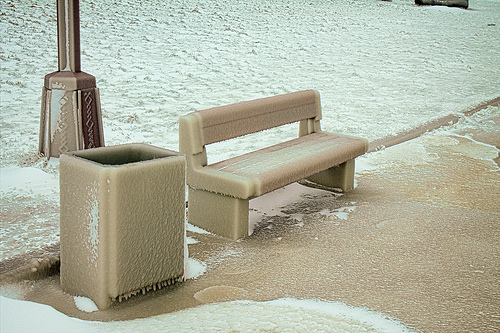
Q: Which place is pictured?
A: It is a sidewalk.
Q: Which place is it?
A: It is a sidewalk.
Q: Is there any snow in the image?
A: Yes, there is snow.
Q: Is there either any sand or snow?
A: Yes, there is snow.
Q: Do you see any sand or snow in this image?
A: Yes, there is snow.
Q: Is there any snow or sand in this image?
A: Yes, there is snow.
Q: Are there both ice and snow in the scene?
A: Yes, there are both snow and ice.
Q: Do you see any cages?
A: No, there are no cages.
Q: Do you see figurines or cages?
A: No, there are no cages or figurines.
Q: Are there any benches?
A: Yes, there is a bench.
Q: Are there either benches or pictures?
A: Yes, there is a bench.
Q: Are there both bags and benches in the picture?
A: No, there is a bench but no bags.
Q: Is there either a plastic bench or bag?
A: Yes, there is a plastic bench.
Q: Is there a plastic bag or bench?
A: Yes, there is a plastic bench.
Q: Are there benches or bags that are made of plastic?
A: Yes, the bench is made of plastic.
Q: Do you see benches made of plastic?
A: Yes, there is a bench that is made of plastic.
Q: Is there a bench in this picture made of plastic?
A: Yes, there is a bench that is made of plastic.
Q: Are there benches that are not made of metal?
A: Yes, there is a bench that is made of plastic.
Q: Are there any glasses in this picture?
A: No, there are no glasses.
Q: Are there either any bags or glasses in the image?
A: No, there are no glasses or bags.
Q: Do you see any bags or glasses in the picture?
A: No, there are no glasses or bags.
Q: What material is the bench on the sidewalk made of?
A: The bench is made of plastic.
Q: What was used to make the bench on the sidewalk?
A: The bench is made of plastic.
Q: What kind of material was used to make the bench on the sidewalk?
A: The bench is made of plastic.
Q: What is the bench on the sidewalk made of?
A: The bench is made of plastic.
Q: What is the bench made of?
A: The bench is made of plastic.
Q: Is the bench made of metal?
A: No, the bench is made of plastic.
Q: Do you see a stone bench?
A: No, there is a bench but it is made of plastic.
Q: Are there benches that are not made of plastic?
A: No, there is a bench but it is made of plastic.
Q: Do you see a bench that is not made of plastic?
A: No, there is a bench but it is made of plastic.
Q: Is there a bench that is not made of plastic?
A: No, there is a bench but it is made of plastic.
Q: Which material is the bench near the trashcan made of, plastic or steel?
A: The bench is made of plastic.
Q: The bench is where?
A: The bench is on the sidewalk.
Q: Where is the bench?
A: The bench is on the sidewalk.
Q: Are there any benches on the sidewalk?
A: Yes, there is a bench on the sidewalk.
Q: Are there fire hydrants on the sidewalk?
A: No, there is a bench on the sidewalk.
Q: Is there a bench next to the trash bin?
A: Yes, there is a bench next to the trash bin.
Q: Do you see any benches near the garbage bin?
A: Yes, there is a bench near the garbage bin.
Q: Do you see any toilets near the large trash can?
A: No, there is a bench near the garbage bin.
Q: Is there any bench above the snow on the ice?
A: Yes, there is a bench above the snow.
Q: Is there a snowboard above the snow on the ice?
A: No, there is a bench above the snow.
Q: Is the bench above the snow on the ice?
A: Yes, the bench is above the snow.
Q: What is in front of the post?
A: The bench is in front of the post.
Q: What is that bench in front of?
A: The bench is in front of the post.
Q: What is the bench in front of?
A: The bench is in front of the post.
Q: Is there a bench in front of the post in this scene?
A: Yes, there is a bench in front of the post.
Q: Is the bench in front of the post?
A: Yes, the bench is in front of the post.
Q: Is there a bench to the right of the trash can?
A: Yes, there is a bench to the right of the trash can.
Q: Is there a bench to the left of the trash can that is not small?
A: No, the bench is to the right of the garbage can.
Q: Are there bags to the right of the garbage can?
A: No, there is a bench to the right of the garbage can.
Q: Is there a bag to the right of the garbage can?
A: No, there is a bench to the right of the garbage can.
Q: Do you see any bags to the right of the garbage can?
A: No, there is a bench to the right of the garbage can.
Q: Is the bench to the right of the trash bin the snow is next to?
A: Yes, the bench is to the right of the garbage bin.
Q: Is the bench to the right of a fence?
A: No, the bench is to the right of the garbage bin.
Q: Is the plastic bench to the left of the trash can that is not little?
A: No, the bench is to the right of the garbage can.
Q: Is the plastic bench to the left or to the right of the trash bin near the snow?
A: The bench is to the right of the trash can.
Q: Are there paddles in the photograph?
A: No, there are no paddles.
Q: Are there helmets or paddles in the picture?
A: No, there are no paddles or helmets.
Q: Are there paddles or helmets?
A: No, there are no paddles or helmets.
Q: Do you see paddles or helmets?
A: No, there are no paddles or helmets.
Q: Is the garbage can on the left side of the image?
A: Yes, the garbage can is on the left of the image.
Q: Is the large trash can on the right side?
A: No, the trashcan is on the left of the image.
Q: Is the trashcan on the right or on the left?
A: The trashcan is on the left of the image.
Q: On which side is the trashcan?
A: The trashcan is on the left of the image.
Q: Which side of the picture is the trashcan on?
A: The trashcan is on the left of the image.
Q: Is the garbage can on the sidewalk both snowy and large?
A: Yes, the trash bin is snowy and large.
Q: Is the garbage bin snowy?
A: Yes, the garbage bin is snowy.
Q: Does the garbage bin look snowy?
A: Yes, the garbage bin is snowy.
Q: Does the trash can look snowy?
A: Yes, the trash can is snowy.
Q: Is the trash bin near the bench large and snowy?
A: Yes, the trash can is large and snowy.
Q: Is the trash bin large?
A: Yes, the trash bin is large.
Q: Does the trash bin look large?
A: Yes, the trash bin is large.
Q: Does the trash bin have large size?
A: Yes, the trash bin is large.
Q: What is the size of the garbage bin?
A: The garbage bin is large.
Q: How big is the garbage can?
A: The garbage can is large.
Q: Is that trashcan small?
A: No, the trashcan is large.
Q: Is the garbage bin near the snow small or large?
A: The garbage can is large.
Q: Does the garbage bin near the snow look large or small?
A: The garbage can is large.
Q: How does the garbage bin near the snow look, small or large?
A: The garbage can is large.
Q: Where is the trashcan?
A: The trashcan is on the sidewalk.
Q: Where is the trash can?
A: The trashcan is on the sidewalk.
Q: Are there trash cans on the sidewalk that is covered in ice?
A: Yes, there is a trash can on the side walk.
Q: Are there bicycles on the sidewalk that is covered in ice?
A: No, there is a trash can on the side walk.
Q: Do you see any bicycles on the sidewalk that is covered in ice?
A: No, there is a trash can on the side walk.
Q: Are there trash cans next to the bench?
A: Yes, there is a trash can next to the bench.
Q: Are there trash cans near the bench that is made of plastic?
A: Yes, there is a trash can near the bench.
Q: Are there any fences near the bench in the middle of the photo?
A: No, there is a trash can near the bench.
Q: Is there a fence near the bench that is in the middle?
A: No, there is a trash can near the bench.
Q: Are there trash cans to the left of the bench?
A: Yes, there is a trash can to the left of the bench.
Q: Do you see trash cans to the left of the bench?
A: Yes, there is a trash can to the left of the bench.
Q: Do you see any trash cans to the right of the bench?
A: No, the trash can is to the left of the bench.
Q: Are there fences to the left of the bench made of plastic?
A: No, there is a trash can to the left of the bench.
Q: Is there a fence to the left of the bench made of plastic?
A: No, there is a trash can to the left of the bench.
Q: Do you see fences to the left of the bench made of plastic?
A: No, there is a trash can to the left of the bench.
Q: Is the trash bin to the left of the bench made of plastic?
A: Yes, the trash bin is to the left of the bench.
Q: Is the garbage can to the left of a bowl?
A: No, the garbage can is to the left of the bench.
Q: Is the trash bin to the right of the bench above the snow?
A: No, the trash bin is to the left of the bench.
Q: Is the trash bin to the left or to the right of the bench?
A: The trash bin is to the left of the bench.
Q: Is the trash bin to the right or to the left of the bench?
A: The trash bin is to the left of the bench.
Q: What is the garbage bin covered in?
A: The garbage bin is covered in ice.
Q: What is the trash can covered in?
A: The garbage bin is covered in ice.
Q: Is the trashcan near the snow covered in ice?
A: Yes, the trash can is covered in ice.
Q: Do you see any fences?
A: No, there are no fences.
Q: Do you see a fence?
A: No, there are no fences.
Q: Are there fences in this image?
A: No, there are no fences.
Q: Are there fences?
A: No, there are no fences.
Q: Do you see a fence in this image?
A: No, there are no fences.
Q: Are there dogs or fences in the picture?
A: No, there are no fences or dogs.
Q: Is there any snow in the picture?
A: Yes, there is snow.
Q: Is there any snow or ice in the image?
A: Yes, there is snow.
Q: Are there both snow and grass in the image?
A: Yes, there are both snow and grass.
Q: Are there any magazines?
A: No, there are no magazines.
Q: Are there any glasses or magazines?
A: No, there are no magazines or glasses.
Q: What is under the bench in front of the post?
A: The snow is under the bench.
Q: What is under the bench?
A: The snow is under the bench.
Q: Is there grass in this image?
A: Yes, there is grass.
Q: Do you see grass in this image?
A: Yes, there is grass.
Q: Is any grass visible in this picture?
A: Yes, there is grass.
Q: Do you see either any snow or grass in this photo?
A: Yes, there is grass.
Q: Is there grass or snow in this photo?
A: Yes, there is grass.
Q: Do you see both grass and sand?
A: No, there is grass but no sand.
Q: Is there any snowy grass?
A: Yes, there is snowy grass.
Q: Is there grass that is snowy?
A: Yes, there is grass that is snowy.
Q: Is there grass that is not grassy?
A: Yes, there is snowy grass.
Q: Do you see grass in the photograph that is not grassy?
A: Yes, there is snowy grass.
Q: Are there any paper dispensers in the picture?
A: No, there are no paper dispensers.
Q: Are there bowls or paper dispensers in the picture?
A: No, there are no paper dispensers or bowls.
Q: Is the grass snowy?
A: Yes, the grass is snowy.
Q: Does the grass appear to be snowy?
A: Yes, the grass is snowy.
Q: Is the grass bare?
A: No, the grass is snowy.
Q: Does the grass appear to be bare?
A: No, the grass is snowy.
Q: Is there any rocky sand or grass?
A: No, there is grass but it is snowy.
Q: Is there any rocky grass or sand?
A: No, there is grass but it is snowy.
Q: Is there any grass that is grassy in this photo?
A: No, there is grass but it is snowy.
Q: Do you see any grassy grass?
A: No, there is grass but it is snowy.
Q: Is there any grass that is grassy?
A: No, there is grass but it is snowy.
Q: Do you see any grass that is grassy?
A: No, there is grass but it is snowy.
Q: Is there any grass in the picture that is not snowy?
A: No, there is grass but it is snowy.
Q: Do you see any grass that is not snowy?
A: No, there is grass but it is snowy.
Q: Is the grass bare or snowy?
A: The grass is snowy.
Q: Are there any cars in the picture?
A: No, there are no cars.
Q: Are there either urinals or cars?
A: No, there are no cars or urinals.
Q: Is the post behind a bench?
A: Yes, the post is behind a bench.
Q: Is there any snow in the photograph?
A: Yes, there is snow.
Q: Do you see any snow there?
A: Yes, there is snow.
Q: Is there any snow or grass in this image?
A: Yes, there is snow.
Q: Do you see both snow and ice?
A: Yes, there are both snow and ice.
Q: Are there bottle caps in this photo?
A: No, there are no bottle caps.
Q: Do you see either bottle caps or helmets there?
A: No, there are no bottle caps or helmets.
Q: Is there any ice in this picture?
A: Yes, there is ice.